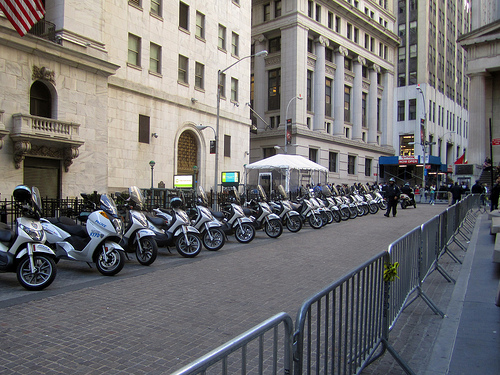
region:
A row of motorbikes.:
[0, 177, 420, 293]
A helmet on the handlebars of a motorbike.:
[13, 183, 36, 202]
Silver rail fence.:
[109, 179, 495, 374]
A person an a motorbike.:
[400, 179, 417, 211]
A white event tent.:
[249, 150, 331, 202]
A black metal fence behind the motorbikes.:
[1, 187, 240, 237]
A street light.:
[204, 48, 269, 218]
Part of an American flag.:
[1, 0, 49, 36]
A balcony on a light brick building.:
[16, 77, 84, 169]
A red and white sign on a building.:
[397, 153, 420, 165]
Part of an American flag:
[0, 0, 55, 36]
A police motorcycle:
[56, 193, 134, 277]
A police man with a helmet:
[377, 176, 405, 221]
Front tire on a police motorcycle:
[94, 243, 127, 276]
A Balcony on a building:
[8, 61, 87, 173]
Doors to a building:
[173, 120, 209, 190]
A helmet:
[4, 181, 36, 219]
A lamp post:
[146, 157, 158, 207]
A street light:
[196, 120, 221, 137]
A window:
[147, 33, 164, 77]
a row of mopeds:
[3, 172, 397, 293]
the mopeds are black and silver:
[0, 172, 393, 286]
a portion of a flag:
[0, 0, 54, 42]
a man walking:
[376, 173, 404, 225]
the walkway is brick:
[4, 202, 468, 373]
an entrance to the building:
[165, 117, 211, 206]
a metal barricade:
[144, 187, 480, 372]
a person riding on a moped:
[396, 180, 421, 210]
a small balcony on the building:
[8, 63, 85, 175]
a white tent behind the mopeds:
[239, 147, 346, 234]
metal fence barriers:
[279, 198, 469, 365]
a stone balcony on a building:
[7, 102, 102, 184]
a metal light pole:
[185, 41, 275, 222]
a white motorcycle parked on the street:
[26, 179, 146, 298]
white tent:
[240, 129, 340, 201]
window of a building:
[15, 71, 77, 123]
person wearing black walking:
[357, 155, 414, 242]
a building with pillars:
[281, 67, 413, 139]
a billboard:
[214, 160, 256, 196]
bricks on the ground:
[227, 232, 319, 297]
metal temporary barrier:
[343, 211, 461, 324]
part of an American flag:
[0, 2, 53, 35]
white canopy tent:
[234, 147, 331, 185]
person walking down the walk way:
[379, 170, 402, 218]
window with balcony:
[8, 69, 88, 157]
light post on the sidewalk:
[196, 40, 271, 193]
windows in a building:
[299, 27, 393, 150]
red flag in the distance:
[451, 151, 468, 168]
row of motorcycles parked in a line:
[50, 193, 282, 268]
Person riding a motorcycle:
[400, 182, 419, 211]